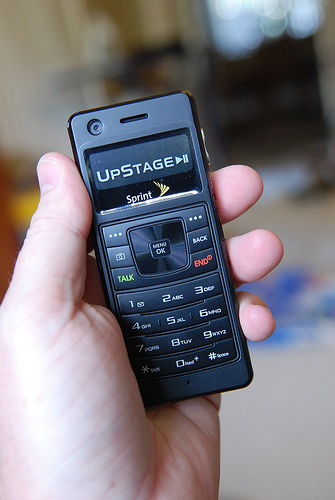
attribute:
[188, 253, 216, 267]
end button — red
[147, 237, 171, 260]
button — green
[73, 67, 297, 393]
phone — black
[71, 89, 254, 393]
phone — black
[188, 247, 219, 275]
end button — red